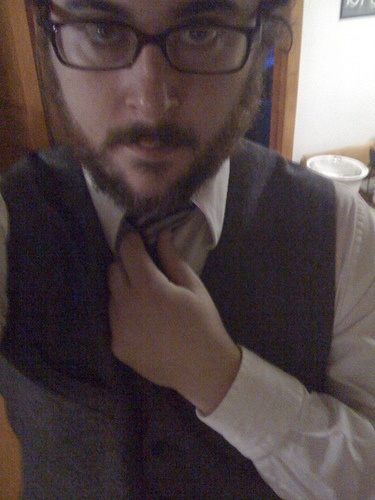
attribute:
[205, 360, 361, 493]
sleeve — white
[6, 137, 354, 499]
vest — gray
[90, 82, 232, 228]
beard — brown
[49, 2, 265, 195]
face — man's face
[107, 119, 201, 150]
brown mustache — dark brown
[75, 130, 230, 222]
beard — dark brown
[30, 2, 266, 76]
glasses — black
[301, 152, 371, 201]
crockpot — white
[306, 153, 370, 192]
cup — white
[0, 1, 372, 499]
man — dressed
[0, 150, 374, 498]
shirt — white